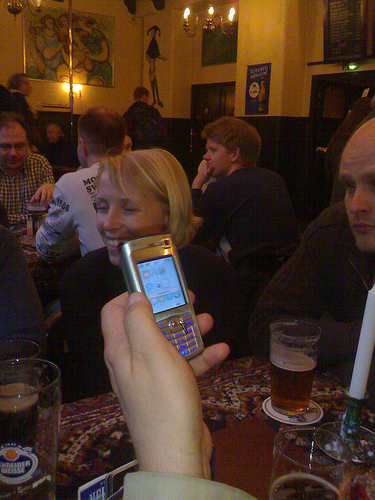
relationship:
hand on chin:
[187, 158, 214, 190] [206, 165, 228, 178]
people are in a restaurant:
[7, 89, 374, 251] [8, 11, 370, 238]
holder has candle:
[324, 388, 372, 473] [350, 279, 373, 399]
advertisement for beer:
[243, 59, 274, 119] [254, 72, 271, 117]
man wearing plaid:
[1, 120, 57, 233] [4, 162, 51, 205]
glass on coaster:
[263, 315, 326, 423] [259, 391, 329, 432]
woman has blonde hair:
[88, 150, 202, 277] [115, 149, 215, 247]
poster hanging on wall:
[139, 18, 173, 111] [34, 6, 316, 115]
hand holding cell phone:
[92, 296, 230, 465] [117, 230, 207, 368]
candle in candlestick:
[350, 279, 373, 399] [324, 388, 372, 473]